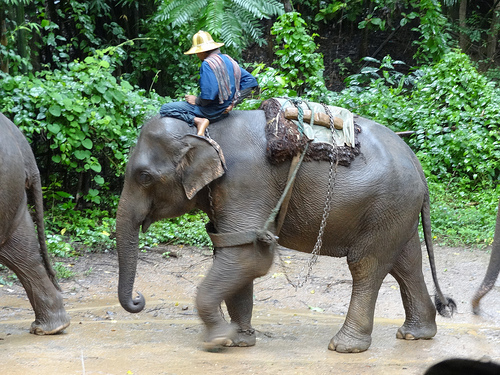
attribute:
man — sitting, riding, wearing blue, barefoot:
[160, 22, 258, 139]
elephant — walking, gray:
[114, 108, 460, 354]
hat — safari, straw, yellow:
[176, 29, 225, 54]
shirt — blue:
[192, 52, 255, 115]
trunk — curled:
[106, 192, 150, 315]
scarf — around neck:
[207, 56, 243, 100]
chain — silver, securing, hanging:
[275, 102, 337, 286]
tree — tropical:
[157, 2, 285, 51]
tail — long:
[421, 175, 457, 322]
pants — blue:
[154, 104, 227, 125]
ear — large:
[172, 133, 227, 203]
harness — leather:
[205, 153, 305, 257]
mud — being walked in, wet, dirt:
[4, 242, 498, 372]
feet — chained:
[192, 230, 274, 351]